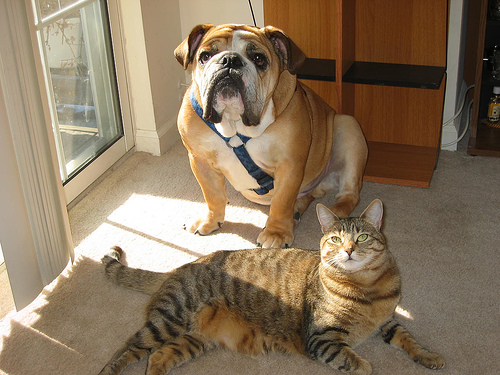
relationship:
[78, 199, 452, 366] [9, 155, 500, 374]
cat on floor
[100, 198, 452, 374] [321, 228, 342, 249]
cat with eye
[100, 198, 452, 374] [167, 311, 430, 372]
cat on ground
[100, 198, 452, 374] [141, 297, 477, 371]
cat on ground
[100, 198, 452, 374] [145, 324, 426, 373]
cat on ground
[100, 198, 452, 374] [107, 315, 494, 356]
cat on ground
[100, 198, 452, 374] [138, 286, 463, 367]
cat on ground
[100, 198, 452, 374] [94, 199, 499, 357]
cat on floor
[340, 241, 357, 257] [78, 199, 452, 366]
nose of a cat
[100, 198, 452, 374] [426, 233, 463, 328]
cat laying on carpet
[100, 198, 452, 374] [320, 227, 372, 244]
cat has eyes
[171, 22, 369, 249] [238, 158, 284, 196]
dog wearing harness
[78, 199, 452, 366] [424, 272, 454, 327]
cat on carpet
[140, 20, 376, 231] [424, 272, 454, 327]
dog on carpet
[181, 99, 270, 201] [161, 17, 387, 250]
strap on dog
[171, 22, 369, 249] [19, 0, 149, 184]
dog next to door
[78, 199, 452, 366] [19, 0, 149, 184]
cat next to door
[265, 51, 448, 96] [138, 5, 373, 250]
shelf behind dog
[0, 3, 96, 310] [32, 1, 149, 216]
blinds on door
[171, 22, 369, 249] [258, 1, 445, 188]
dog sitting on shelf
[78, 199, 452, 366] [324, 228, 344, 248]
cat has an eye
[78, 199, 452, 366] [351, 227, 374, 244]
cat has an eye